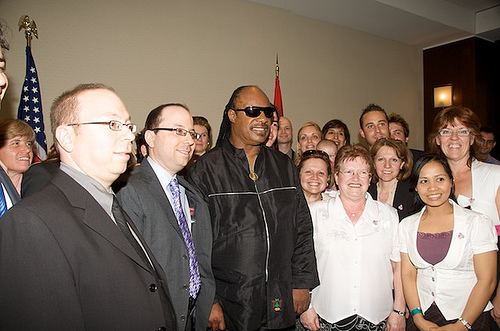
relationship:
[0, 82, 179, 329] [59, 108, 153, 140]
guy in glasses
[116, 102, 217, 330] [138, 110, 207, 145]
man in glasses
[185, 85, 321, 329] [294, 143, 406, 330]
black man alongside person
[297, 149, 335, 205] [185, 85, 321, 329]
person behind black man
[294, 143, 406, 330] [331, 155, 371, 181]
person with glasses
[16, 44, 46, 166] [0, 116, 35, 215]
flag behind woman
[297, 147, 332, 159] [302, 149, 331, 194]
sunglasses on top of head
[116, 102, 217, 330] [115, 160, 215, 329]
man in suit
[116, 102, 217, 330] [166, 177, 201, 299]
man with neck tie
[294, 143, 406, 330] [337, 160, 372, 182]
person with glasses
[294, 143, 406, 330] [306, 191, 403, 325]
person in blouse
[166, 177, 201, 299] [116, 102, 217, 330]
neck tie on man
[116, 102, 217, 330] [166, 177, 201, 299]
man wearing a neck tie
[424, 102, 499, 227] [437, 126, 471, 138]
woman with glasses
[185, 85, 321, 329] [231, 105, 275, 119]
black man with sunglasses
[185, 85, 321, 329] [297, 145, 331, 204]
black man standing with person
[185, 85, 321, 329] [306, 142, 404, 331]
black man standing with person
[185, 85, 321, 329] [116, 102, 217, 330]
black man standing with man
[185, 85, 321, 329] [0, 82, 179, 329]
black man standing with guy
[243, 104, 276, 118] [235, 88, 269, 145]
glasses on face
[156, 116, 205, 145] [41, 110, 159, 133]
glasses on man's face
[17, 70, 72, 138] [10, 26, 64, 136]
stars on flag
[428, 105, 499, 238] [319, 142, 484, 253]
woman looking at camera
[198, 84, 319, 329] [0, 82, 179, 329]
black man surrounded guy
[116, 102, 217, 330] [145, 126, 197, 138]
man wearing glasses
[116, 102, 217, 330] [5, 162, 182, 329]
man wearing suit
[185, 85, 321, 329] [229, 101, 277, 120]
black man wearing sunglasses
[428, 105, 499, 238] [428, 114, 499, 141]
woman wearing glasses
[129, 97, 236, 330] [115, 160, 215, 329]
man wearing suit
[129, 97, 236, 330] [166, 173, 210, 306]
man wearing tie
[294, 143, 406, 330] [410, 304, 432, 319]
person wearing bracelet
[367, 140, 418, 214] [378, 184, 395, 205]
woman wearing shirt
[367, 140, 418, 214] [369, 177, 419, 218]
woman wearing blazer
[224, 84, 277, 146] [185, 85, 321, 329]
head of black man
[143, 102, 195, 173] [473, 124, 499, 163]
head of man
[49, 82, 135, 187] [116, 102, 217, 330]
head of man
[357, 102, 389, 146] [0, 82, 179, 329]
head of guy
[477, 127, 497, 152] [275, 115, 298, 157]
head of man